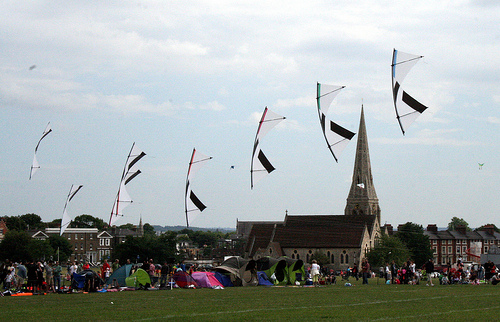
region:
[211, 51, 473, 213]
several kites are flying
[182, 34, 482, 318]
several kites are flying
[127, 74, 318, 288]
several kites are flying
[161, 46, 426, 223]
row of identical kites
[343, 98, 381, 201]
church steeple on horizon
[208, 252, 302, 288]
tents pitched on grass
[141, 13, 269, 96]
clouds in daytime sky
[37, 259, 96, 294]
peope standing on a field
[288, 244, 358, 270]
windows on side of church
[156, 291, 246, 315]
neatly trimmed green grass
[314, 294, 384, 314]
white line on grass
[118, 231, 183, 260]
trees with green leaves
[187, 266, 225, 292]
pink tent on grass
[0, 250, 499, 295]
people on a field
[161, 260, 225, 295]
a tent is pink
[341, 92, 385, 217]
tower on a building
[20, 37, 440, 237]
seven kites in the sky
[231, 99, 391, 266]
a church in the city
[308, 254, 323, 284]
a person wearing a white top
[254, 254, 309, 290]
a green tent on a field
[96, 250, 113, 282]
person has a red long sleeve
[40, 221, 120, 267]
a building in front of church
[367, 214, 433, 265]
trees in front of church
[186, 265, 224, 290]
ONE PINK TENT IN THE FIELD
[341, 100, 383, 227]
CHURCH STEEPLE IS TALL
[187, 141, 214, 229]
KITE IS RED, BLACK AND WHITE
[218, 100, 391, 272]
A CHURCH IN THE BACKGROUND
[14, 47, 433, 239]
SEVEN KITES FLYING IN THE SKY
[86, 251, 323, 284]
SPECTATORS ARE STAYING IN TENTS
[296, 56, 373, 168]
BLUE, BLACK AND WHITE KITE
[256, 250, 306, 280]
TWO GREEN IDENTICAL TENTS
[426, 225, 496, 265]
RED BUILDINGS TO THE RIGHT OF CHURCH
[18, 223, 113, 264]
BROWN BUILDING TO LEFT OF CHURCH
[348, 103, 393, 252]
STEEPLE OF CHURCH IS TALL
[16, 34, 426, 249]
SEVEN KITES ARE BEING FLOWN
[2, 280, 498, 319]
GRASS IN FOREGROUND IS GREEN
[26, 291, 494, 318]
WHITE LINES ARE ON THE GRASS AREA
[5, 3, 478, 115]
BLUE SKY HAS WHITE CLOUDS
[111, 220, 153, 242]
SECOND CHURCH IS IN THE BACKGROUND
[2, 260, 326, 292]
SPECTATORS ARE STAYING IN TENTS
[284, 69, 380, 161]
BLUE, BLACK AND WHITE COLORED TENT